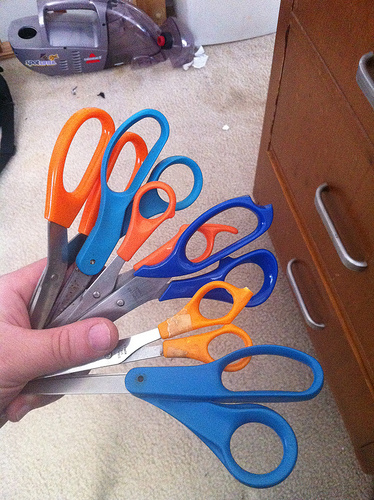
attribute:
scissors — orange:
[42, 275, 270, 381]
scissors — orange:
[18, 90, 156, 336]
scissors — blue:
[59, 174, 294, 340]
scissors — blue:
[43, 112, 213, 311]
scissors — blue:
[39, 343, 333, 474]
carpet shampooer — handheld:
[12, 7, 203, 71]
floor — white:
[5, 41, 362, 496]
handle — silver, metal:
[302, 173, 373, 290]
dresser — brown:
[238, 9, 371, 472]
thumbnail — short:
[82, 321, 117, 355]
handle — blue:
[129, 345, 324, 478]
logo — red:
[80, 43, 104, 71]